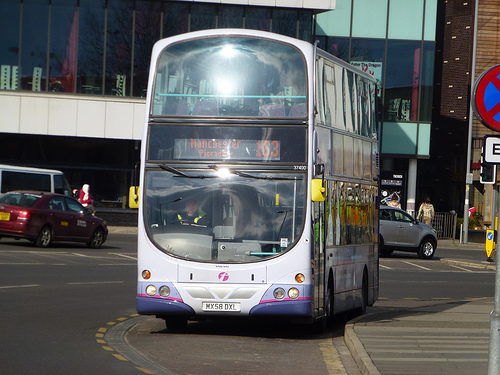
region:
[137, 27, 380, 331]
A double stack bus on the road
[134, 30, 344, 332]
Front end of a double stack bus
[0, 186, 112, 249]
A burgundy car on the road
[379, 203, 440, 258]
A silver car on the road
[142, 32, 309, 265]
The front windshield on a double stack bus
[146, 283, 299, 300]
Front headlights on a bus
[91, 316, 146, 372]
Segmented line painted on a road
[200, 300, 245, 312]
Front license plate on a bus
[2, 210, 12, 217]
Yellow license plate on a car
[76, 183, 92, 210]
A lady in red walking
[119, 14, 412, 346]
A bus in the foreground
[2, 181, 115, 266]
A red car in the background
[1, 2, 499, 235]
A building in the background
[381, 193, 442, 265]
A side view of a silver car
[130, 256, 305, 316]
Busses headlights are on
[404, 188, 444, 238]
A person in the background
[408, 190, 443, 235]
Person is turned away from the camera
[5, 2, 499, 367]
Photo was taken in the daytime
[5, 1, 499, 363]
Photo was taken outside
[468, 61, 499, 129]
red and blue circular sign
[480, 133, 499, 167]
white and black street sign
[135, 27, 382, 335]
white bus in the street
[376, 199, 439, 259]
silver car in the street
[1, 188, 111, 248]
red car in the street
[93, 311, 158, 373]
yellow lines in the street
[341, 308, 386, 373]
gray curb along the street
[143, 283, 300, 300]
headlights on the bus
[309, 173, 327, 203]
yellow side mirror on the bus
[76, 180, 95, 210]
person wearing red and white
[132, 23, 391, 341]
A double decker bus in the street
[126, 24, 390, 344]
A double decker bus in the street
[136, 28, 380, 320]
Two story bus on the street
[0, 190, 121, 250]
Red car on the street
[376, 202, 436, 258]
Grey car on the street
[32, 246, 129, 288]
Lines painted on the road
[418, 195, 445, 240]
A person walking on the sidewalk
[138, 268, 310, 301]
Lights on a two story bus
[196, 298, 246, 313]
Licence plates on a two story bus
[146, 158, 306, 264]
Windshield on a two story bus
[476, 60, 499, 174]
Sign on the side of the road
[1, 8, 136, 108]
Glass window on a building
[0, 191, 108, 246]
the car is dark red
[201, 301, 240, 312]
the license plate is white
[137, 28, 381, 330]
the bus is a double decker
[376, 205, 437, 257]
the car is gray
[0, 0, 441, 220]
the building has a lot of windows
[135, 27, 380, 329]
the bus has a lot of windows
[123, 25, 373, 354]
white and purple double deck passenger bus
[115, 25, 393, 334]
white and purple double deck bus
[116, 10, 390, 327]
white and purple passenger bus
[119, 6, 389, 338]
white and purple bus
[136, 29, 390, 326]
white double deck passenger bus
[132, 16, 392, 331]
white double deck bus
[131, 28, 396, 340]
white passenger bus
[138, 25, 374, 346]
bus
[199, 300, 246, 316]
black and white license plate number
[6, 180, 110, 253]
burgundy car